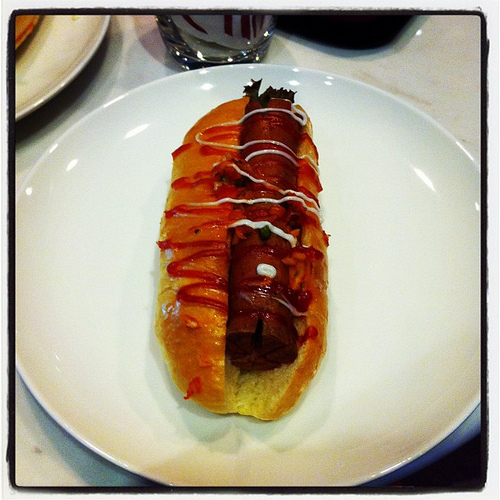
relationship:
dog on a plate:
[243, 96, 287, 357] [20, 61, 485, 488]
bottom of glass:
[163, 36, 273, 56] [166, 19, 264, 65]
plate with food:
[20, 61, 485, 488] [158, 82, 328, 426]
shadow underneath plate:
[430, 447, 490, 497] [388, 219, 451, 413]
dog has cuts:
[227, 91, 301, 370] [245, 310, 270, 370]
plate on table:
[20, 61, 485, 488] [18, 49, 478, 486]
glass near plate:
[154, 10, 279, 62] [20, 61, 485, 488]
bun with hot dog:
[151, 95, 331, 422] [225, 77, 304, 372]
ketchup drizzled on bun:
[156, 125, 329, 341] [151, 76, 335, 421]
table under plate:
[40, 438, 74, 468] [20, 61, 485, 488]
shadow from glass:
[132, 18, 168, 73] [155, 18, 281, 67]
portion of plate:
[171, 82, 321, 177] [20, 61, 485, 488]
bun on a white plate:
[151, 76, 335, 421] [9, 59, 479, 487]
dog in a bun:
[227, 91, 301, 370] [151, 95, 331, 422]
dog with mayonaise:
[227, 91, 301, 370] [195, 103, 324, 245]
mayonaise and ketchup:
[195, 103, 324, 245] [156, 125, 329, 341]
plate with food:
[20, 61, 485, 488] [144, 69, 352, 451]